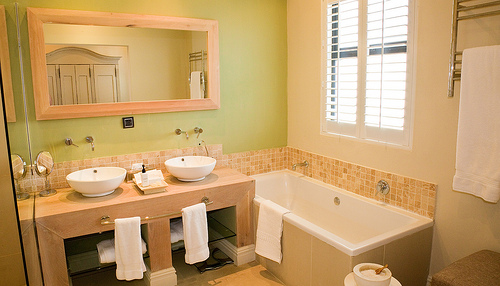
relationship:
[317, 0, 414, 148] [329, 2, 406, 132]
blinds on window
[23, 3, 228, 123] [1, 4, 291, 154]
mirror for wall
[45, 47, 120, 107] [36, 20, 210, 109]
door reflection in mirror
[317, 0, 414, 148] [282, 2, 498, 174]
blinds on wall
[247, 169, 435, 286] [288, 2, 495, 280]
bathtub against wall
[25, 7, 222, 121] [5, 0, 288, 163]
mirror hanging on wall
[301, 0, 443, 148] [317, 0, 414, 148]
blinds in front of blinds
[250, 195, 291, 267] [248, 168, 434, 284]
towel hanging on bathtub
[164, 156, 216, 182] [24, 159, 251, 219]
sink on top of counter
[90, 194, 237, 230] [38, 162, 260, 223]
rack in counter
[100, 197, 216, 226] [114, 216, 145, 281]
rack in tangle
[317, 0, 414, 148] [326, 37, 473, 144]
blinds in blinds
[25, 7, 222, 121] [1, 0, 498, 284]
mirror in bathroom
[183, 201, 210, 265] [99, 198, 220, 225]
towel in rack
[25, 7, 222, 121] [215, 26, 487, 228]
mirror in wall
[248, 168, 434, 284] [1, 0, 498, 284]
bathtub in bathroom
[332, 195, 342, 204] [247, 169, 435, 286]
drain for bathtub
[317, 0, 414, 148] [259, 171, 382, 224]
blinds above bathtub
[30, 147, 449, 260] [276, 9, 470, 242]
tile on wall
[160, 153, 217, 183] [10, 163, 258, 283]
sink in counter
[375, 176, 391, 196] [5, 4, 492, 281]
knob in bath